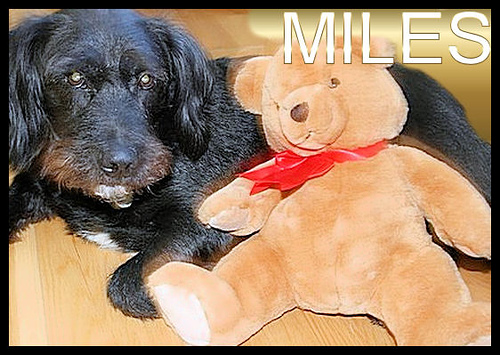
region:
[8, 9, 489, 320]
black dog with floppy ears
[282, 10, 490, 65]
MILES is the name of the dog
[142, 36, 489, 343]
teddy bear with a red ribbon around its neck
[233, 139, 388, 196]
red ribbon tied in a bow around a teddy bear's neck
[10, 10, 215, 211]
head of a black dog with floppy ears and a white chin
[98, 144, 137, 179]
nose of a dog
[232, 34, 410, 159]
head of a teddy bear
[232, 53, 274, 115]
ear of a teddy bear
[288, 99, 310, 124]
nose of a teddy bear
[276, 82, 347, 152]
snout of a teddy bear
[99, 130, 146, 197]
nose of the dog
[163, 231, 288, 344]
leg of the bear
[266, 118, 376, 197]
red band around bear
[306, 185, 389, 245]
brown fur on bear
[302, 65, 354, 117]
eye of the bear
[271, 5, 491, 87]
name in top right corner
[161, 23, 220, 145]
ear of the dog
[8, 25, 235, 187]
dog looking at the camera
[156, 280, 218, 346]
bottom of the bear's foot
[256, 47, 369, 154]
head of the bear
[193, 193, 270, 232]
paw of the bear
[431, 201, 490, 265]
paw of the bear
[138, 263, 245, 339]
paw of the bear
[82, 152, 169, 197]
nose of the dog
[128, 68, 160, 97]
eye of the dgo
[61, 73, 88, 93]
eye of the dog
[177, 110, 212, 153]
ear of the dog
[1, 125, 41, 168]
ear of the dog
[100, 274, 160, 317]
paw of the dog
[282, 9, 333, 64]
white print style letter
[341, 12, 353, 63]
white print style letter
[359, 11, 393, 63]
white print style letter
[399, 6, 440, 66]
white print style letter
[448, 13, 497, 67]
white print style letter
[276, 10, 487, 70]
white print style letters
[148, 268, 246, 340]
brown teddy bear paw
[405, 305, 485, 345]
brown teddy bear paw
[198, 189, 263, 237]
brown teddy bear paw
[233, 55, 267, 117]
brown teddy bear ear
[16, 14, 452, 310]
a dog beside a teddy bear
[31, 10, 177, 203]
the head of a dog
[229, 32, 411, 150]
the head of a teddy bear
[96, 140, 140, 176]
the nose of a dog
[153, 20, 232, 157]
the ear of a dog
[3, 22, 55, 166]
the ear of a dog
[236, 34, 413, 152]
the head of a teddy bear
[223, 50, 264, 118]
the ear of a teddy bear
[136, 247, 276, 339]
the leg of a teddy bear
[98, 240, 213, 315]
the leg of a dog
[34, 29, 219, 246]
a black dog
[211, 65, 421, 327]
brown bare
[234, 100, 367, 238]
red bow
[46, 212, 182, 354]
wood floor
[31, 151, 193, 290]
A white patch on the black dog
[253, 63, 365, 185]
A bear with brown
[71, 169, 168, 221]
White patch on dogs mouth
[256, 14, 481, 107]
The word miles in white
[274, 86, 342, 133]
Brown nose on the bear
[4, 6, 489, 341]
Portrait of animal with toy.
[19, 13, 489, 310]
Black dog with white tummy patch, lying down.